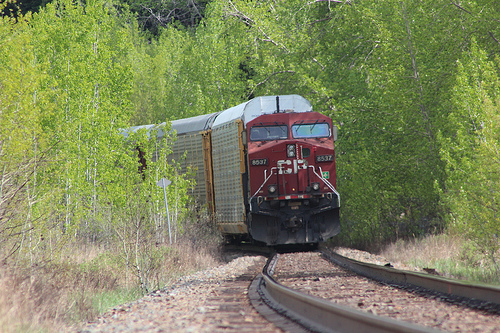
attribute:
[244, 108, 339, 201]
paint — red, white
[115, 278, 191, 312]
stones — tiny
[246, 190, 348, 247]
metal plate — black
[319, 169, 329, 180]
green symbol — white, small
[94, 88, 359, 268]
train — red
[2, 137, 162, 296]
bushes — old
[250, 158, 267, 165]
number — white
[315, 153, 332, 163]
number — white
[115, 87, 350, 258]
train — bottom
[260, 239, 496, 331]
tracks — rusty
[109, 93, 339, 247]
train — black, red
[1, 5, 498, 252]
trees — very light green, green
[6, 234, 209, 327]
grass — brown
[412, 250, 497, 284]
grass — green